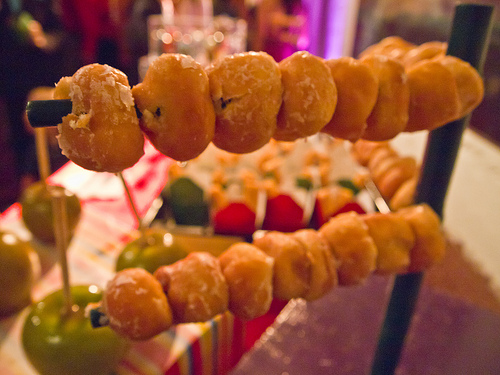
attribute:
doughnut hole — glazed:
[277, 48, 338, 147]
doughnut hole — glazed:
[219, 241, 276, 316]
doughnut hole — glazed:
[406, 54, 461, 135]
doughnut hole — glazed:
[54, 63, 144, 172]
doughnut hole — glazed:
[130, 53, 213, 162]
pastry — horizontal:
[102, 203, 443, 339]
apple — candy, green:
[19, 280, 117, 372]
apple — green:
[9, 272, 158, 373]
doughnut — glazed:
[199, 47, 283, 158]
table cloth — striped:
[1, 129, 266, 374]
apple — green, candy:
[1, 228, 39, 318]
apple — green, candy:
[22, 179, 81, 246]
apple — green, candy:
[114, 229, 186, 275]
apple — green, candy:
[20, 281, 130, 373]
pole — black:
[400, 38, 482, 307]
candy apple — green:
[27, 197, 121, 373]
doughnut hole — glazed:
[97, 263, 176, 343]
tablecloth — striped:
[0, 85, 362, 372]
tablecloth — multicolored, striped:
[0, 128, 287, 373]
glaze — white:
[95, 66, 133, 110]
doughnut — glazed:
[132, 48, 218, 166]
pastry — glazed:
[52, 59, 148, 180]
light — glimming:
[87, 282, 102, 295]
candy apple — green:
[113, 225, 185, 279]